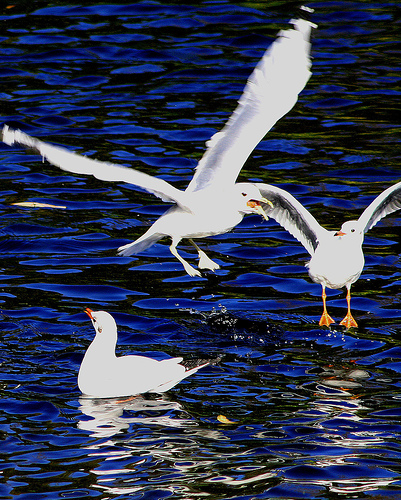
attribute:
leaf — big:
[219, 415, 240, 421]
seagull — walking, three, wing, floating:
[33, 286, 226, 422]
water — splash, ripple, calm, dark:
[199, 286, 261, 337]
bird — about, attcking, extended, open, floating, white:
[113, 27, 315, 257]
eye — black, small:
[239, 178, 262, 203]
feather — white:
[260, 70, 293, 117]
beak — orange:
[319, 218, 360, 246]